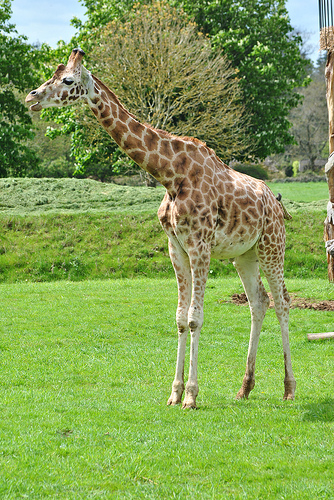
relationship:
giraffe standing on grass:
[23, 49, 303, 409] [9, 176, 330, 496]